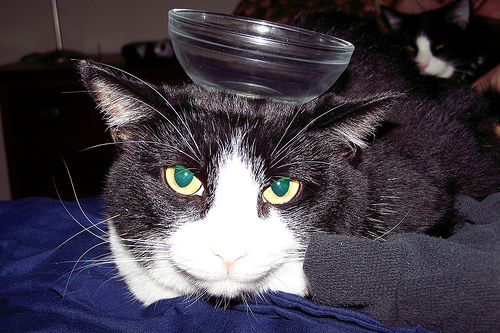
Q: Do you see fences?
A: No, there are no fences.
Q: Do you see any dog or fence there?
A: No, there are no fences or dogs.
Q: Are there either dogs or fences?
A: No, there are no fences or dogs.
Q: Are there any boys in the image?
A: No, there are no boys.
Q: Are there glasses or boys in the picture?
A: No, there are no boys or glasses.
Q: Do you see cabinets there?
A: Yes, there is a cabinet.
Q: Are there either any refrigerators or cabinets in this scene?
A: Yes, there is a cabinet.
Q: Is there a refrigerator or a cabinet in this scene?
A: Yes, there is a cabinet.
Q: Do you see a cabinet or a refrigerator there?
A: Yes, there is a cabinet.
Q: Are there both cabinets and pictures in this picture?
A: No, there is a cabinet but no pictures.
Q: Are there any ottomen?
A: No, there are no ottomen.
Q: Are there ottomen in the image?
A: No, there are no ottomen.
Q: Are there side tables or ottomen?
A: No, there are no ottomen or side tables.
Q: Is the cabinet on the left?
A: Yes, the cabinet is on the left of the image.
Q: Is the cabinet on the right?
A: No, the cabinet is on the left of the image.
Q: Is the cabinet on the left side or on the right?
A: The cabinet is on the left of the image.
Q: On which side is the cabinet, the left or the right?
A: The cabinet is on the left of the image.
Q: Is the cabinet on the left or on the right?
A: The cabinet is on the left of the image.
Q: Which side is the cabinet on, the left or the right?
A: The cabinet is on the left of the image.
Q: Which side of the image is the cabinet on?
A: The cabinet is on the left of the image.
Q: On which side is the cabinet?
A: The cabinet is on the left of the image.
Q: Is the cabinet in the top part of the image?
A: Yes, the cabinet is in the top of the image.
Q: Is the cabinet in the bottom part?
A: No, the cabinet is in the top of the image.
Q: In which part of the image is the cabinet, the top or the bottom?
A: The cabinet is in the top of the image.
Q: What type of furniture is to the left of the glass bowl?
A: The piece of furniture is a cabinet.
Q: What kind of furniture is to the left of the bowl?
A: The piece of furniture is a cabinet.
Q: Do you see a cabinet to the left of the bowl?
A: Yes, there is a cabinet to the left of the bowl.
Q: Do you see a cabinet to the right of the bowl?
A: No, the cabinet is to the left of the bowl.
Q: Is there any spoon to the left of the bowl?
A: No, there is a cabinet to the left of the bowl.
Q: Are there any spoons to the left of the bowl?
A: No, there is a cabinet to the left of the bowl.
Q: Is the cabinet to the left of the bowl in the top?
A: Yes, the cabinet is to the left of the bowl.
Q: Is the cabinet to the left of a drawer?
A: No, the cabinet is to the left of the bowl.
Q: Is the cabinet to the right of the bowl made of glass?
A: No, the cabinet is to the left of the bowl.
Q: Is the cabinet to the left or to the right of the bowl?
A: The cabinet is to the left of the bowl.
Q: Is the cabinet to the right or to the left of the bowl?
A: The cabinet is to the left of the bowl.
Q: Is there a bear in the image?
A: No, there are no bears.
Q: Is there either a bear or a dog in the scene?
A: No, there are no bears or dogs.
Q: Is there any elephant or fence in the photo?
A: No, there are no fences or elephants.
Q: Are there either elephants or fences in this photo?
A: No, there are no fences or elephants.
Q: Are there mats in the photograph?
A: No, there are no mats.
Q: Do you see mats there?
A: No, there are no mats.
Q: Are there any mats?
A: No, there are no mats.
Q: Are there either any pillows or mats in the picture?
A: No, there are no mats or pillows.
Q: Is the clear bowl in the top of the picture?
A: Yes, the bowl is in the top of the image.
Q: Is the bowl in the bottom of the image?
A: No, the bowl is in the top of the image.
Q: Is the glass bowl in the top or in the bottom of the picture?
A: The bowl is in the top of the image.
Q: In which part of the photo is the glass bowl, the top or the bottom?
A: The bowl is in the top of the image.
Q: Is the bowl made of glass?
A: Yes, the bowl is made of glass.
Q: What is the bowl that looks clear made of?
A: The bowl is made of glass.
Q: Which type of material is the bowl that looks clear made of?
A: The bowl is made of glass.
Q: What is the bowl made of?
A: The bowl is made of glass.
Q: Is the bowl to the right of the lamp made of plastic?
A: No, the bowl is made of glass.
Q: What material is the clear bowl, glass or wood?
A: The bowl is made of glass.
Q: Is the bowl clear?
A: Yes, the bowl is clear.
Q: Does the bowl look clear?
A: Yes, the bowl is clear.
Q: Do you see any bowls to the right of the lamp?
A: Yes, there is a bowl to the right of the lamp.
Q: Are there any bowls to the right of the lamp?
A: Yes, there is a bowl to the right of the lamp.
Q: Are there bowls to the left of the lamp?
A: No, the bowl is to the right of the lamp.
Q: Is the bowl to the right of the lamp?
A: Yes, the bowl is to the right of the lamp.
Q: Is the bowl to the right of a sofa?
A: No, the bowl is to the right of the lamp.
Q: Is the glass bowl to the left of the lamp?
A: No, the bowl is to the right of the lamp.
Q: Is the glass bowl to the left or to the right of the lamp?
A: The bowl is to the right of the lamp.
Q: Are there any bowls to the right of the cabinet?
A: Yes, there is a bowl to the right of the cabinet.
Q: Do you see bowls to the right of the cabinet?
A: Yes, there is a bowl to the right of the cabinet.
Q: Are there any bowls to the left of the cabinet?
A: No, the bowl is to the right of the cabinet.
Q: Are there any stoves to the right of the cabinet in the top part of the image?
A: No, there is a bowl to the right of the cabinet.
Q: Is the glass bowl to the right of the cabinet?
A: Yes, the bowl is to the right of the cabinet.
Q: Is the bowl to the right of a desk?
A: No, the bowl is to the right of the cabinet.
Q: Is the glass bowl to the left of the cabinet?
A: No, the bowl is to the right of the cabinet.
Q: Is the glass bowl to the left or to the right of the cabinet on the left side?
A: The bowl is to the right of the cabinet.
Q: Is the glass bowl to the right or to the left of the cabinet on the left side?
A: The bowl is to the right of the cabinet.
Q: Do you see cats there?
A: Yes, there is a cat.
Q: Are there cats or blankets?
A: Yes, there is a cat.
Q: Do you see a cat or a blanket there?
A: Yes, there is a cat.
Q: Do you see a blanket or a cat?
A: Yes, there is a cat.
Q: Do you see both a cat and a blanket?
A: Yes, there are both a cat and a blanket.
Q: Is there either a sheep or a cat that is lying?
A: Yes, the cat is lying.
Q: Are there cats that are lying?
A: Yes, there is a cat that is lying.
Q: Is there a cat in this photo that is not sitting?
A: Yes, there is a cat that is lying.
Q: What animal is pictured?
A: The animal is a cat.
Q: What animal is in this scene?
A: The animal is a cat.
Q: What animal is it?
A: The animal is a cat.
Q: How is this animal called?
A: This is a cat.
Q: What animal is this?
A: This is a cat.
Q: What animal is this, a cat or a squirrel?
A: This is a cat.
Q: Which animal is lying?
A: The animal is a cat.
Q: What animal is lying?
A: The animal is a cat.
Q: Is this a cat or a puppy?
A: This is a cat.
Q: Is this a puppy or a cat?
A: This is a cat.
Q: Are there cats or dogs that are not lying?
A: No, there is a cat but it is lying.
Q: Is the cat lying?
A: Yes, the cat is lying.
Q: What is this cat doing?
A: The cat is lying.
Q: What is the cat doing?
A: The cat is lying.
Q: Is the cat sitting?
A: No, the cat is lying.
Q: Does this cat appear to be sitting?
A: No, the cat is lying.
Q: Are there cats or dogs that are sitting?
A: No, there is a cat but it is lying.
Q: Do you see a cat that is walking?
A: No, there is a cat but it is lying.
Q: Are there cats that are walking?
A: No, there is a cat but it is lying.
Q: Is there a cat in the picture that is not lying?
A: No, there is a cat but it is lying.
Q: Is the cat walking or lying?
A: The cat is lying.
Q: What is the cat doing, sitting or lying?
A: The cat is lying.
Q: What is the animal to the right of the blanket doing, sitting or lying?
A: The cat is lying.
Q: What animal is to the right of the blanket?
A: The animal is a cat.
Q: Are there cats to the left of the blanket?
A: No, the cat is to the right of the blanket.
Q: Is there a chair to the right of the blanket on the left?
A: No, there is a cat to the right of the blanket.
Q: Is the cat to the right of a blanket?
A: Yes, the cat is to the right of a blanket.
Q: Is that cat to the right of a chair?
A: No, the cat is to the right of a blanket.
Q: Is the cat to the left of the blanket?
A: No, the cat is to the right of the blanket.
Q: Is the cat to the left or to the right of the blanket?
A: The cat is to the right of the blanket.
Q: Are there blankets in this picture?
A: Yes, there is a blanket.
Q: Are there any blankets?
A: Yes, there is a blanket.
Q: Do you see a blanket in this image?
A: Yes, there is a blanket.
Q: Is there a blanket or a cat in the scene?
A: Yes, there is a blanket.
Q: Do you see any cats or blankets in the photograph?
A: Yes, there is a blanket.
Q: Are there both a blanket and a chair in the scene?
A: No, there is a blanket but no chairs.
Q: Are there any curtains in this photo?
A: No, there are no curtains.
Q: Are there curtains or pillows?
A: No, there are no curtains or pillows.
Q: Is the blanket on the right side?
A: No, the blanket is on the left of the image.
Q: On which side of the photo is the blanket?
A: The blanket is on the left of the image.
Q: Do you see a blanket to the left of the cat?
A: Yes, there is a blanket to the left of the cat.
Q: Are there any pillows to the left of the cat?
A: No, there is a blanket to the left of the cat.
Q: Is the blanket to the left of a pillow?
A: No, the blanket is to the left of a cat.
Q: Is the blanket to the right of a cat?
A: No, the blanket is to the left of a cat.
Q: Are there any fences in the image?
A: No, there are no fences.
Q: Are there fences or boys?
A: No, there are no fences or boys.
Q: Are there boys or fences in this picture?
A: No, there are no fences or boys.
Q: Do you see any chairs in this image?
A: No, there are no chairs.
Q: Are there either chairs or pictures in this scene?
A: No, there are no chairs or pictures.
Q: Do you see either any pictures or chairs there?
A: No, there are no chairs or pictures.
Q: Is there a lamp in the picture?
A: Yes, there is a lamp.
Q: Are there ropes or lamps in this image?
A: Yes, there is a lamp.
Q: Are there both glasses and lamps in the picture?
A: No, there is a lamp but no glasses.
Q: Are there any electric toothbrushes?
A: No, there are no electric toothbrushes.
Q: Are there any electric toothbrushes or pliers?
A: No, there are no electric toothbrushes or pliers.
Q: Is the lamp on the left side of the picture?
A: Yes, the lamp is on the left of the image.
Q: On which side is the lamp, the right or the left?
A: The lamp is on the left of the image.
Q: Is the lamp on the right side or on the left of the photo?
A: The lamp is on the left of the image.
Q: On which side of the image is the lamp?
A: The lamp is on the left of the image.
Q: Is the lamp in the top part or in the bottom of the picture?
A: The lamp is in the top of the image.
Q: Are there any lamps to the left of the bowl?
A: Yes, there is a lamp to the left of the bowl.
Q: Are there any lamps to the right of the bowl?
A: No, the lamp is to the left of the bowl.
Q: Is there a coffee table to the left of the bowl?
A: No, there is a lamp to the left of the bowl.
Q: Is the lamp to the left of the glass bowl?
A: Yes, the lamp is to the left of the bowl.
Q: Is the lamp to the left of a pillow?
A: No, the lamp is to the left of the bowl.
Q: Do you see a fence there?
A: No, there are no fences.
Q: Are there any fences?
A: No, there are no fences.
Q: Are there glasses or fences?
A: No, there are no fences or glasses.